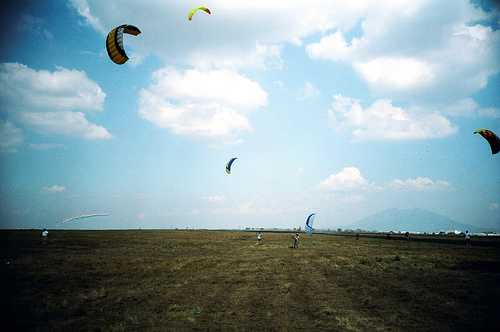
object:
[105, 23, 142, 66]
kite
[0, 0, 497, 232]
sky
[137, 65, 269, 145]
cloud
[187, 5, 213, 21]
kite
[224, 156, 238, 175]
kite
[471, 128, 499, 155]
kite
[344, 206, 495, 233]
mountain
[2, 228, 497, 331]
field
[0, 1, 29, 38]
corner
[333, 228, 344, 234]
trees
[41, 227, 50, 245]
man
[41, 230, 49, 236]
shirt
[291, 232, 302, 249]
man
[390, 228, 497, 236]
city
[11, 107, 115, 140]
cloud